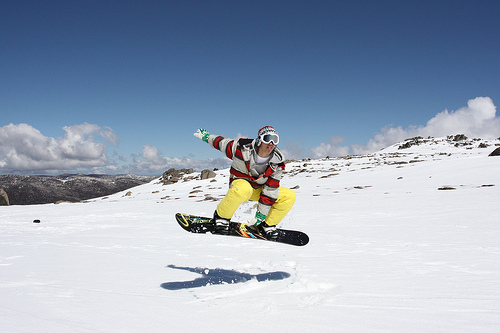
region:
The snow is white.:
[395, 232, 447, 308]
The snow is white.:
[358, 276, 390, 330]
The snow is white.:
[368, 181, 420, 267]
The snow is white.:
[328, 238, 394, 332]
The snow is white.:
[334, 243, 379, 308]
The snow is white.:
[349, 188, 434, 306]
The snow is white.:
[398, 260, 462, 328]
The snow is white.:
[362, 226, 457, 300]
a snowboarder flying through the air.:
[167, 106, 332, 245]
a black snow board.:
[170, 204, 309, 251]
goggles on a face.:
[247, 121, 296, 161]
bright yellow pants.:
[209, 179, 298, 220]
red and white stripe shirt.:
[205, 140, 292, 197]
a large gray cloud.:
[0, 121, 122, 176]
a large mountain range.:
[0, 170, 151, 207]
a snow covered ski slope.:
[0, 135, 497, 325]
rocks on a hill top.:
[375, 118, 490, 171]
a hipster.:
[253, 127, 280, 149]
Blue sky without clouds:
[3, 8, 498, 105]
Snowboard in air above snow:
[175, 210, 302, 246]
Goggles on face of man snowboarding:
[256, 130, 279, 145]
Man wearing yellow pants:
[225, 180, 295, 220]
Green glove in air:
[191, 121, 209, 138]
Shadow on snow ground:
[145, 258, 300, 289]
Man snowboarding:
[167, 117, 313, 248]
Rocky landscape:
[330, 131, 490, 178]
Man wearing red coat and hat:
[200, 126, 280, 206]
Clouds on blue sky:
[0, 117, 155, 171]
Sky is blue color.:
[101, 36, 313, 78]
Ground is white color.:
[88, 258, 199, 323]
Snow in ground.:
[28, 249, 108, 306]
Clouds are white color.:
[0, 128, 93, 162]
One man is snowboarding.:
[175, 122, 310, 242]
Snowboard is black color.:
[173, 208, 314, 247]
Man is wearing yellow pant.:
[219, 183, 299, 233]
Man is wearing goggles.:
[258, 129, 280, 154]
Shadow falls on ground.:
[157, 255, 290, 300]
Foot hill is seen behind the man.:
[2, 167, 142, 195]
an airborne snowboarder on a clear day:
[169, 112, 312, 252]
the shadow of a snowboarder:
[160, 261, 290, 292]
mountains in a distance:
[0, 170, 144, 205]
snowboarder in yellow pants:
[194, 126, 294, 231]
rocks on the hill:
[157, 162, 219, 185]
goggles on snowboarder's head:
[259, 132, 280, 146]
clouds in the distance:
[0, 120, 110, 175]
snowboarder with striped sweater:
[193, 127, 293, 236]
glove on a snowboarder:
[191, 126, 208, 139]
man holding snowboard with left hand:
[175, 125, 309, 244]